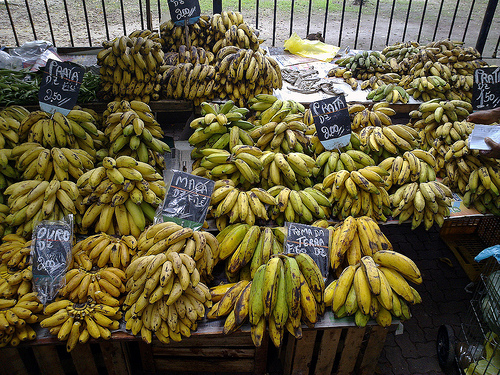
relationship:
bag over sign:
[13, 47, 45, 65] [309, 94, 350, 152]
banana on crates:
[227, 154, 261, 185] [271, 275, 419, 371]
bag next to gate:
[279, 25, 381, 81] [1, 0, 499, 71]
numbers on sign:
[286, 81, 386, 201] [309, 94, 350, 152]